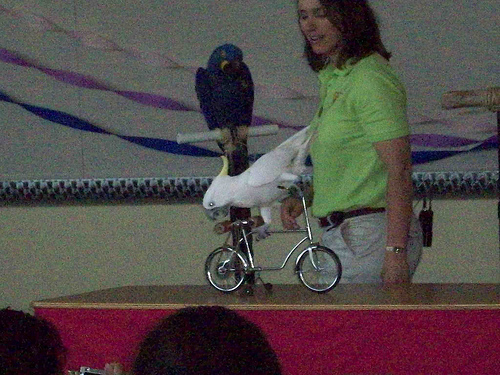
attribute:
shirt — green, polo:
[306, 53, 408, 215]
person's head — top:
[286, 4, 394, 57]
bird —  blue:
[193, 42, 256, 154]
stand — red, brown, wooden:
[32, 282, 497, 372]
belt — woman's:
[314, 200, 391, 231]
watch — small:
[386, 244, 410, 258]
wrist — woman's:
[371, 232, 425, 274]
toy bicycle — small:
[202, 195, 339, 301]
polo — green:
[306, 48, 420, 217]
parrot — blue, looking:
[190, 26, 267, 184]